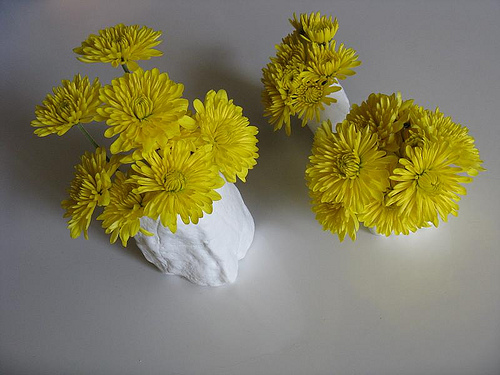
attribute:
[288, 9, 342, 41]
flower — yellow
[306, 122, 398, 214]
flower — single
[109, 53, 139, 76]
stem — green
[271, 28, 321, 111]
flower — yellow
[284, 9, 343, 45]
flower — yellow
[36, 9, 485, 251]
flowers — yellow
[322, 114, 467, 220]
flowers — yellow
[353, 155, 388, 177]
petals — spread out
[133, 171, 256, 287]
container — white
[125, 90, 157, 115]
middle — yellow and green, of flower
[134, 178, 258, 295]
white vase — medium sized 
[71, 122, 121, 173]
stem — green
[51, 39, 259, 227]
flower — yellow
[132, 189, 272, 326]
vases — white 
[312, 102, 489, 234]
flower — yellow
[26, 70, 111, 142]
flower — yellow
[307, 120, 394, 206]
flower — yellow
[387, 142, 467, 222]
flower — yellow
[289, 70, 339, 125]
flower — yellow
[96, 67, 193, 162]
flower — yellow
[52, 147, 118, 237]
flower — yellow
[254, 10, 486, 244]
flowers — two sets , different sets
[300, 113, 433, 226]
yellow flowers — small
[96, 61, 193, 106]
petals — many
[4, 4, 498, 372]
table — gray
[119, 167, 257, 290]
vases — different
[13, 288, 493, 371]
background — white 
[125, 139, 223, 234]
flower — sunflower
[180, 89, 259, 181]
flower — sunflower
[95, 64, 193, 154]
flower — yellow, sunflower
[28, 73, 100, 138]
flower — sunflower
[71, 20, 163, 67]
flower — sunflower